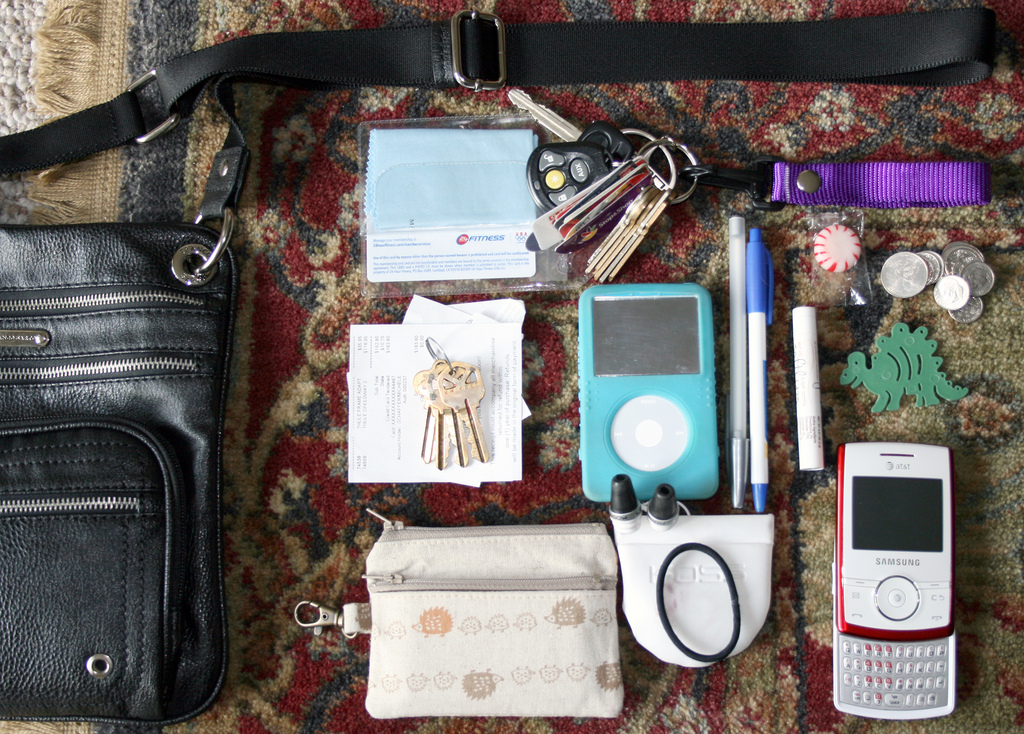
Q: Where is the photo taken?
A: On a rug on a floor.